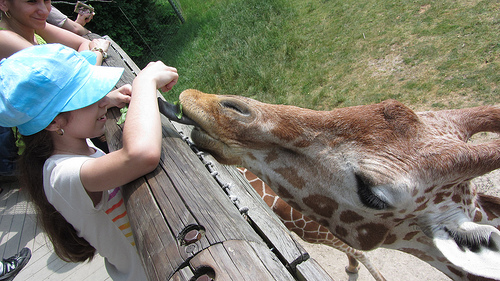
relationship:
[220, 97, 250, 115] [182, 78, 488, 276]
nostril on giraffe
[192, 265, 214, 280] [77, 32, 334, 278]
bolt in fence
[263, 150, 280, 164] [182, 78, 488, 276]
spot on giraffe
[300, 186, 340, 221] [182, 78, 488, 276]
spot on giraffe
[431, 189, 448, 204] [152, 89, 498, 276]
spot on giraffe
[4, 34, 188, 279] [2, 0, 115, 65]
girl next to person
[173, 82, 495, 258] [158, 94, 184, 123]
giraffe sticking out tongue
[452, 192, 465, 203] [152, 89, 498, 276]
spot on giraffe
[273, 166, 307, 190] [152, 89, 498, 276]
spot on giraffe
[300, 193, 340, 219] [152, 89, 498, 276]
spot on giraffe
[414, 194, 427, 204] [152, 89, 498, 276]
spot on giraffe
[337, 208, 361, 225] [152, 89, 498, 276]
spot on giraffe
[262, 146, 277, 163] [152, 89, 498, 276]
spot on giraffe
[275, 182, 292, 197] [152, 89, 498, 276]
spot on giraffe